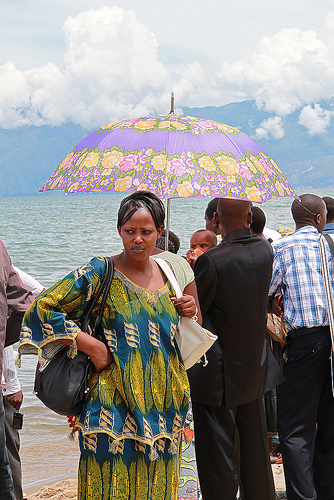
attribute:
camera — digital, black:
[9, 408, 24, 430]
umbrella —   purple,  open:
[37, 92, 299, 202]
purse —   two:
[151, 257, 218, 371]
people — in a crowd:
[20, 104, 333, 498]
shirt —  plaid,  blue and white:
[278, 207, 333, 345]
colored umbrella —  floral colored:
[56, 100, 251, 195]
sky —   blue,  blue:
[1, 1, 330, 188]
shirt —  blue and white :
[268, 225, 332, 327]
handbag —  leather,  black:
[33, 255, 114, 416]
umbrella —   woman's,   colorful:
[35, 111, 302, 203]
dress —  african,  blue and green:
[14, 256, 189, 496]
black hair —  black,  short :
[117, 190, 165, 228]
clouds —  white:
[217, 30, 316, 109]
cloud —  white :
[252, 113, 286, 145]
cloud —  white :
[295, 101, 331, 142]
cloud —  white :
[53, 2, 167, 121]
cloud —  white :
[216, 21, 332, 120]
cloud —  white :
[1, 56, 34, 131]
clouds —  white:
[185, 25, 267, 108]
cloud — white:
[0, 62, 30, 111]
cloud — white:
[30, 59, 65, 130]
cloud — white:
[69, 1, 162, 89]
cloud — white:
[258, 106, 285, 141]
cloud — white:
[229, 24, 330, 99]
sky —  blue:
[1, 3, 333, 139]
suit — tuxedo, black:
[189, 225, 279, 495]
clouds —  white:
[144, 22, 315, 109]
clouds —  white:
[63, 26, 126, 84]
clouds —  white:
[9, 72, 57, 121]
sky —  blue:
[5, 9, 65, 62]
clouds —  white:
[215, 26, 332, 115]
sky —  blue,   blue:
[2, 3, 332, 110]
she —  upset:
[14, 189, 199, 499]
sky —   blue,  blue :
[6, 3, 327, 99]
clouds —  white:
[220, 28, 332, 139]